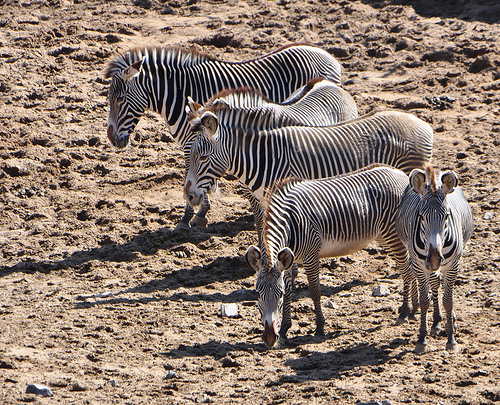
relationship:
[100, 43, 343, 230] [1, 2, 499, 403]
zebra are on bare ground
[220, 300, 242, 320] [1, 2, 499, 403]
rock on bare ground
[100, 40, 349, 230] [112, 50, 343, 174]
zebra has stripes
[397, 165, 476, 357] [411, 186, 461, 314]
zebra has stripes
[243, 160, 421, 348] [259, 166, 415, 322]
zebra has stripes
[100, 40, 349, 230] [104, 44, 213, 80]
zebra has mane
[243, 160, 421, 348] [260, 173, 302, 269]
zebra has mane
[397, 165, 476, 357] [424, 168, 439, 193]
zebra has mane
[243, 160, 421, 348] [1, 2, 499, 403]
zebra sniffing bare ground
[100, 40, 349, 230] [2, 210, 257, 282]
zebra has shadow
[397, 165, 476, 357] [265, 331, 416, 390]
zebra has shadow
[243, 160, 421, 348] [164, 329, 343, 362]
zebra has shadow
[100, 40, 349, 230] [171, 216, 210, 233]
zebra has hooves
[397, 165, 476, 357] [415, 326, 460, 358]
zebra has hooves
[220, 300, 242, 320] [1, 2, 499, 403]
rock on dirt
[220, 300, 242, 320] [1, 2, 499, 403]
rock in dirt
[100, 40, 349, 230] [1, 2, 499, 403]
zebra standing on dirt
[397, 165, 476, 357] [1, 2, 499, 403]
zebra standing on dirt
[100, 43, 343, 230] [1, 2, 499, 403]
zebra standing on dirt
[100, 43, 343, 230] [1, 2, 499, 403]
zebra in desert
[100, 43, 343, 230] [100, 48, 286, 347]
zebra are looking sideways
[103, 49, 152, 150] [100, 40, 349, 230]
head of zebra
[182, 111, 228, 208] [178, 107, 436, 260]
head of zebra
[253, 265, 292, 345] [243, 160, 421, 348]
head of zebra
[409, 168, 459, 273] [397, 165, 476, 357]
head of zebra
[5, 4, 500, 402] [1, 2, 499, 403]
dirt clumps on ground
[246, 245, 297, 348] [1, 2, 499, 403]
zebra head near ground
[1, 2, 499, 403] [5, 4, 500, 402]
dirt has clumps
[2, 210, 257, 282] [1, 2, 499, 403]
shadow on ground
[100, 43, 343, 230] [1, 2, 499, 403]
zebra standing in dirt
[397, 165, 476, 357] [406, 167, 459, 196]
zebra has ears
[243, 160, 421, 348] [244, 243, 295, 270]
zebra has ears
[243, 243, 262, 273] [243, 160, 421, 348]
ear belonging to zebra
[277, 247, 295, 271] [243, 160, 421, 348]
ear belonging to zebra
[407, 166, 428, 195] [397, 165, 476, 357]
ear belonging to zebra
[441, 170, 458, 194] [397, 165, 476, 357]
ear belonging to zebra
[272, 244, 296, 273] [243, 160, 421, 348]
ear belonging to zebra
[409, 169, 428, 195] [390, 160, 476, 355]
ear belonging to zebra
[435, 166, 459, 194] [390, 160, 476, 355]
ear belonging to zebra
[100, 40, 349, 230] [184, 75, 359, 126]
zebra standing next to zebra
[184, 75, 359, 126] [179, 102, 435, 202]
zebra standing next to zebra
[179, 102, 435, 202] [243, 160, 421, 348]
zebra standing next to zebra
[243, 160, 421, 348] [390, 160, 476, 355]
zebra standing next to zebra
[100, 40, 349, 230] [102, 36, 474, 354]
zebra standing in group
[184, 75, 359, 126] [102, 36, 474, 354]
zebra standing in group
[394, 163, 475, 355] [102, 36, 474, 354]
zebra standing in group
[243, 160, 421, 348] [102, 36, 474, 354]
zebra standing in group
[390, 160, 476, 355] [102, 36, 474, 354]
zebra standing in group